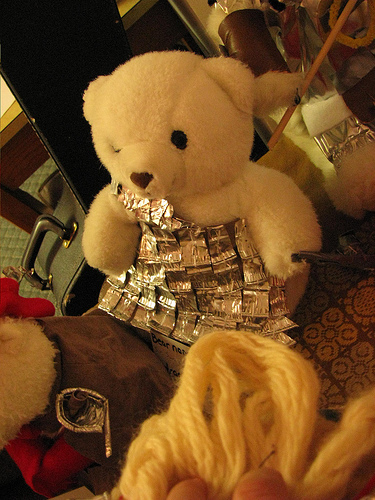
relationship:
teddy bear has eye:
[78, 50, 320, 385] [163, 125, 192, 153]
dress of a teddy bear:
[103, 184, 300, 338] [78, 50, 320, 385]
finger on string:
[164, 477, 206, 499] [178, 383, 205, 476]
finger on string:
[164, 477, 206, 499] [183, 339, 211, 483]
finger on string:
[164, 477, 206, 499] [212, 344, 234, 499]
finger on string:
[164, 477, 206, 499] [212, 346, 246, 499]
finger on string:
[164, 477, 206, 499] [300, 361, 315, 478]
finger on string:
[232, 470, 289, 499] [178, 383, 205, 476]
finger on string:
[232, 470, 289, 499] [183, 339, 211, 483]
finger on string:
[232, 470, 289, 499] [212, 344, 234, 499]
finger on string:
[232, 470, 289, 499] [212, 346, 246, 499]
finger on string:
[232, 470, 289, 499] [300, 361, 315, 478]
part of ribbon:
[183, 342, 197, 365] [173, 326, 279, 468]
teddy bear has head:
[78, 50, 320, 385] [81, 51, 253, 198]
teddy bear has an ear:
[78, 50, 320, 385] [201, 55, 254, 109]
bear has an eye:
[76, 47, 322, 332] [170, 130, 188, 149]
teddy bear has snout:
[78, 50, 320, 385] [130, 172, 155, 191]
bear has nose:
[76, 47, 322, 332] [112, 143, 184, 198]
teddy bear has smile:
[61, 50, 320, 392] [129, 176, 187, 202]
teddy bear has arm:
[78, 50, 320, 385] [242, 162, 321, 277]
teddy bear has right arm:
[78, 50, 320, 385] [72, 172, 148, 294]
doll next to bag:
[81, 50, 321, 315] [15, 188, 101, 314]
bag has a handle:
[15, 188, 101, 314] [17, 213, 78, 290]